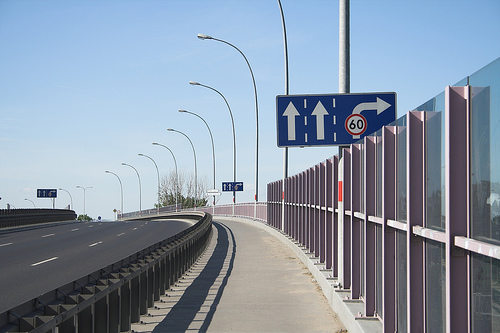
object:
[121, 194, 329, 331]
sidewalk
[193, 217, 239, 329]
shadow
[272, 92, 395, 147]
sign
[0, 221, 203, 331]
freeway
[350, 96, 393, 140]
arrows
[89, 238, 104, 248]
white line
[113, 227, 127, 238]
white line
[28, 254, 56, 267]
white line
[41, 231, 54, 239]
white line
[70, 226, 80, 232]
white line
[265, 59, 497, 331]
wall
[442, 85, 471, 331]
beams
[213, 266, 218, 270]
part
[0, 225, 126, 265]
lanes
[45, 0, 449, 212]
lights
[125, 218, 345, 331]
floor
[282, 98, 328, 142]
arrows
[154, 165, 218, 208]
tree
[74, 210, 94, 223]
tree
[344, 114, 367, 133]
circle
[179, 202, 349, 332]
cement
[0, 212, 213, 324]
guard rail